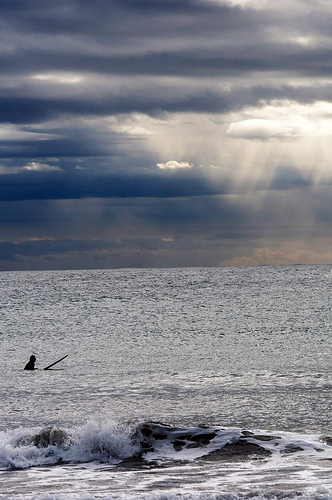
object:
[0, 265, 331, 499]
water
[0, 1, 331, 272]
clouds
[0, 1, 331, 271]
sunlight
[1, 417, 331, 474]
wave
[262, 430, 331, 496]
white foam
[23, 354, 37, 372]
surfer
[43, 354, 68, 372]
surfboard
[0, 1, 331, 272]
sky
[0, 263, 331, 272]
horizon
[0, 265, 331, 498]
ripples